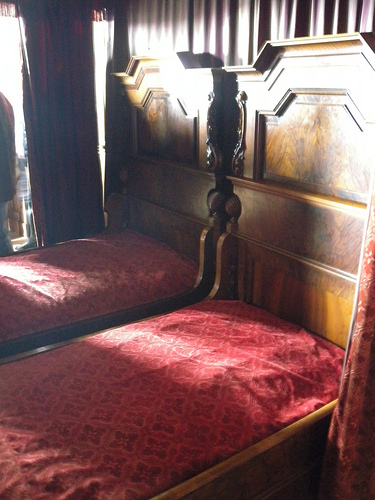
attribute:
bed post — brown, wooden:
[97, 33, 374, 340]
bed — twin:
[0, 51, 216, 372]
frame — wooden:
[156, 395, 342, 499]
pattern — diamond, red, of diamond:
[1, 225, 343, 498]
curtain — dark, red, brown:
[12, 3, 106, 244]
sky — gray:
[0, 17, 25, 99]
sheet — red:
[0, 303, 349, 500]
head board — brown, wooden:
[105, 53, 211, 270]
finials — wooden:
[194, 67, 245, 302]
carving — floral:
[202, 97, 249, 175]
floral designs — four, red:
[196, 400, 216, 421]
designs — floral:
[195, 375, 223, 401]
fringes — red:
[3, 0, 121, 21]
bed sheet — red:
[0, 218, 197, 347]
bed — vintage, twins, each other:
[0, 30, 373, 498]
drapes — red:
[323, 195, 374, 499]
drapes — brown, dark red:
[105, 1, 374, 69]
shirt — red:
[3, 90, 19, 202]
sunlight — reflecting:
[141, 51, 221, 122]